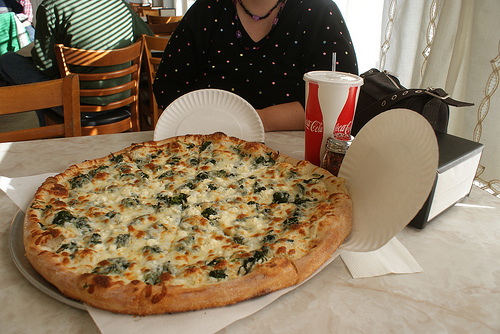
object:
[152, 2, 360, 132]
lady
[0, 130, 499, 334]
table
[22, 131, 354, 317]
pizza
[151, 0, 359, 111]
shirt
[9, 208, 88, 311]
pan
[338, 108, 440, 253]
plate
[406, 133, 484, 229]
holder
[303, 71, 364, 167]
cup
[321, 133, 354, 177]
shaker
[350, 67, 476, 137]
purse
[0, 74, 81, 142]
chair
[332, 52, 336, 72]
straw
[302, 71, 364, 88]
lid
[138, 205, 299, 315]
slice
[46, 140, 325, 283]
toppings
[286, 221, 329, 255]
crust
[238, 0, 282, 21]
necklace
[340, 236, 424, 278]
napkin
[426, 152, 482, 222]
napkins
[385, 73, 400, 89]
zipper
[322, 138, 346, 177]
pepper